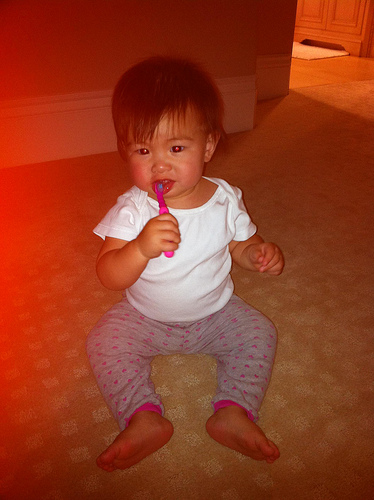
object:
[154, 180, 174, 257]
spoon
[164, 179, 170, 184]
baby teeth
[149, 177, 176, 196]
mouth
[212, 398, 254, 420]
lining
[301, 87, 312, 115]
ground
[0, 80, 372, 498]
carpet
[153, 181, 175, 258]
babyspoon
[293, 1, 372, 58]
cabinet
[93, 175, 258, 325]
shirt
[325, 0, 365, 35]
wooddoor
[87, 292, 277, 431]
pants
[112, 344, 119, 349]
red dots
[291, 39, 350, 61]
rug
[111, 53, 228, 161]
hair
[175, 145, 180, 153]
red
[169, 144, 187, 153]
child's eye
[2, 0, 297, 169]
wall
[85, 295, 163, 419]
legs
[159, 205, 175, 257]
handle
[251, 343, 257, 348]
hearts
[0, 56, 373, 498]
floor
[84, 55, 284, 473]
child